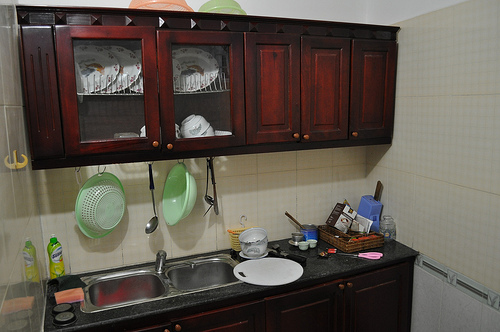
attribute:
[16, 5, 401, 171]
cabinets — wood, reddish, black, overhead, burgandy, wooden, brown, dark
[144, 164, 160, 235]
ladle — hanging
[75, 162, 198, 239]
colanders — green, hanging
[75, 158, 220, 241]
utensils — hanging, together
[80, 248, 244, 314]
sinks — metal, double, stainless, dual, steel, silver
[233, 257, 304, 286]
plate — hanging, white, round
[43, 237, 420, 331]
counter — black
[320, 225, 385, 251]
tray — filled, brown, wicker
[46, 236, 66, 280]
bottle — suave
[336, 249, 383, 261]
scissors — pink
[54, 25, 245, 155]
doors — glass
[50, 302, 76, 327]
stopper — black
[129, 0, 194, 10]
bowl — pink, white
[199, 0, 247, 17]
bowl — green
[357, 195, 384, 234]
block — blue, plastic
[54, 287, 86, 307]
sponge — pink, orange